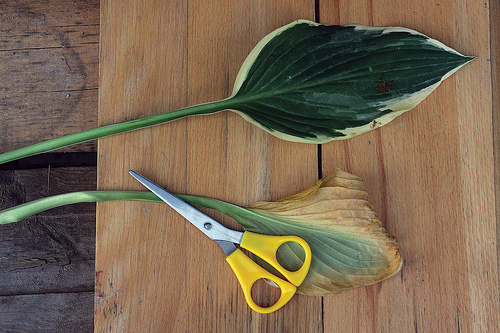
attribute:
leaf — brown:
[236, 31, 413, 143]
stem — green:
[3, 90, 229, 175]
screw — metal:
[376, 232, 427, 278]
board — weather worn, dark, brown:
[99, 15, 217, 78]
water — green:
[224, 17, 476, 152]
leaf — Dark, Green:
[0, 19, 477, 164]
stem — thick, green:
[0, 93, 230, 170]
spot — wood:
[0, 2, 90, 154]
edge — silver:
[130, 172, 240, 259]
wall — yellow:
[210, 101, 218, 150]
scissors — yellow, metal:
[127, 167, 314, 319]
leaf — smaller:
[0, 168, 404, 298]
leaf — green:
[0, 16, 472, 150]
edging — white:
[228, 55, 469, 146]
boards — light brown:
[94, 1, 499, 331]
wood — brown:
[94, 1, 499, 331]